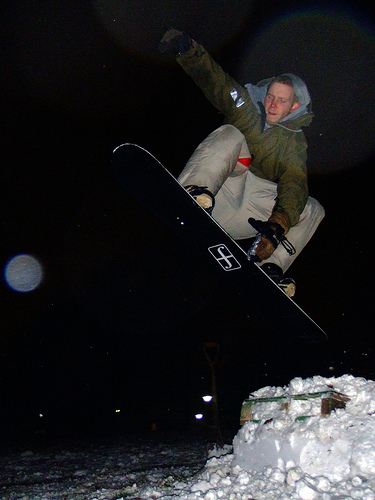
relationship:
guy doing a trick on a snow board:
[177, 73, 320, 217] [112, 143, 328, 341]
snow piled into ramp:
[2, 372, 373, 496] [237, 390, 348, 423]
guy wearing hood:
[158, 29, 325, 297] [245, 71, 315, 129]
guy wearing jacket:
[158, 29, 325, 297] [172, 39, 313, 231]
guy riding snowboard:
[158, 29, 325, 297] [112, 141, 330, 353]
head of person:
[253, 71, 311, 125] [175, 20, 318, 297]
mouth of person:
[264, 106, 283, 124] [196, 33, 334, 306]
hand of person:
[250, 210, 288, 262] [159, 27, 326, 295]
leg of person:
[183, 132, 241, 184] [232, 64, 308, 152]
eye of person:
[276, 97, 287, 106] [159, 27, 326, 295]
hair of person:
[265, 73, 292, 88] [159, 27, 326, 295]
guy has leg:
[158, 29, 325, 297] [231, 228, 312, 303]